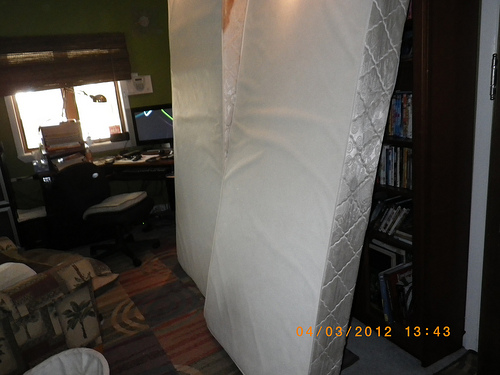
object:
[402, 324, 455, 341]
time of photo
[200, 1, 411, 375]
box spring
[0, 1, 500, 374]
room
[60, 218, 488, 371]
floor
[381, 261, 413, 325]
books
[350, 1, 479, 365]
shelving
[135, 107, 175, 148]
screen saver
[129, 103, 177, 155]
computer monitor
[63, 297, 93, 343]
design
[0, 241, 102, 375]
chair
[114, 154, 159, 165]
computer keyboard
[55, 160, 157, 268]
computer chair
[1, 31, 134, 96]
window blinds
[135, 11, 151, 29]
smoke detector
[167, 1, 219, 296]
part of mattress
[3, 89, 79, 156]
part of window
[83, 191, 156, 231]
edge of seat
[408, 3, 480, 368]
edge of shelf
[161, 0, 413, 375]
two mattresses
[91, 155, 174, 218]
desk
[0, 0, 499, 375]
picture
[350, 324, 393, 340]
2012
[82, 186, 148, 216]
cushion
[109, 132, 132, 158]
lamp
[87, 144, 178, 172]
stuff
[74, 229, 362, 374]
rug